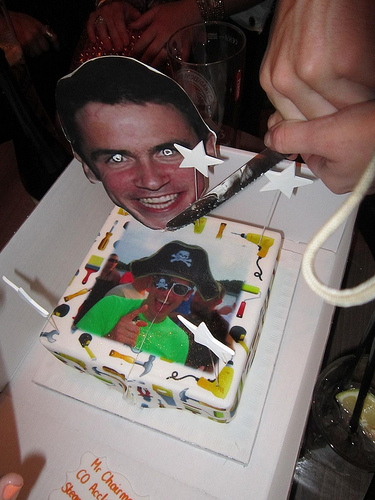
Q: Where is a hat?
A: On the cake.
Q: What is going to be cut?
A: The cake.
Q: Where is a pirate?
A: On the lake.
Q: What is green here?
A: Man's shirt.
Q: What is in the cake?
A: Man in a pirate hat.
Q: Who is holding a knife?
A: One man.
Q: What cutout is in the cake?
A: Cardboard.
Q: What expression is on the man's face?
A: Smile.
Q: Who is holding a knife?
A: A person.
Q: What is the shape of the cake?
A: Rectangle.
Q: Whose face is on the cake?
A: A pirates.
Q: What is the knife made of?
A: Metal.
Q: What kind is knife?
A: Steak knife.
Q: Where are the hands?
A: On right top.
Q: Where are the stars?
A: On both sides of knife.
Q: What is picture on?
A: Table.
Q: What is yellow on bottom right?
A: Drill.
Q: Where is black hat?
A: Man's head.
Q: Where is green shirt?
A: On man with pirate hat.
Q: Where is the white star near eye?
A: Right side of eye.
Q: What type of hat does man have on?
A: Pirate.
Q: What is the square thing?
A: A cake.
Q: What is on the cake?
A: A picture.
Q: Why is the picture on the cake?
A: Decoration.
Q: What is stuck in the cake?
A: WIres.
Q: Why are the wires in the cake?
A: To hold pictures.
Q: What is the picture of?
A: A person's face.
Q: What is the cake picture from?
A: A pirate.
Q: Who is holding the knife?
A: A boy.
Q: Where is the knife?
A: In the man's hands.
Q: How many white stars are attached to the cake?
A: Four.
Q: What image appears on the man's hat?
A: Skull and crossbones.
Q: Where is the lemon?
A: In the glass in the lower right hand corner.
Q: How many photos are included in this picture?
A: Two.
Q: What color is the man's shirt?
A: Green.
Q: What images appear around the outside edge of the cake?
A: Tools.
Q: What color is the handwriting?
A: Orange.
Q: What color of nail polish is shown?
A: Peach.